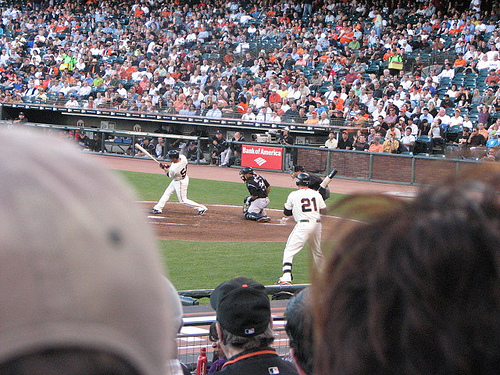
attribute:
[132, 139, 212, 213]
player — swinging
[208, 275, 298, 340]
cap — black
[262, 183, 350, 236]
shirt — white, numbered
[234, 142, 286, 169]
sign — red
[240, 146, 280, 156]
letters — white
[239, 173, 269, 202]
shirt — black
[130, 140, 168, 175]
bat — white